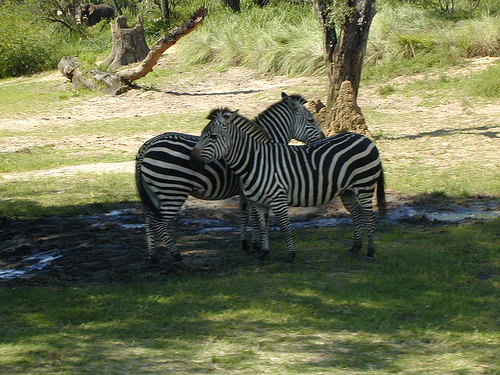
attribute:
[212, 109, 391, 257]
zebra — standing, facing, black, white, striped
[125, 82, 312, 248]
zebra — standing, facing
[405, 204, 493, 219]
water — running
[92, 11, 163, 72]
tree — dead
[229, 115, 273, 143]
mane — fluffy, thick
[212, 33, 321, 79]
grass — green, brown, long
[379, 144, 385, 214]
tail — black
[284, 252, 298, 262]
hoof — black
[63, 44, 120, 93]
branch — broken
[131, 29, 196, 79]
stump — broken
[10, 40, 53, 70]
plant — green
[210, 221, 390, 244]
trail — wet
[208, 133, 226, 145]
eye — black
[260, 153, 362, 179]
stripes — black, white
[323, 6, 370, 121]
tree trunk — brown